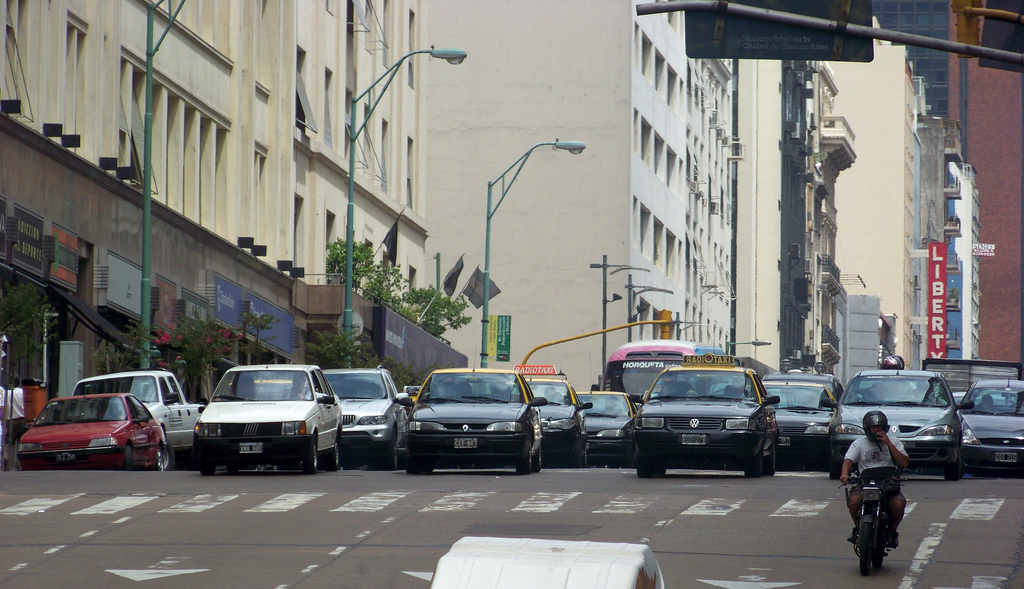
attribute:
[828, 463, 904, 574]
motorcycle — black 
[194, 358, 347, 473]
car — white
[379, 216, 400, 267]
flag — black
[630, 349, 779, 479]
car — black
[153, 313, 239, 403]
tree — green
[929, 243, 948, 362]
sign — red, white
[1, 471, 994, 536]
lines — white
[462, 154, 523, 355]
pole — green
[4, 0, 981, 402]
buildings — row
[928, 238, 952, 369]
sign — white, red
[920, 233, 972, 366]
liberty — White 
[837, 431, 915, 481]
shirt — white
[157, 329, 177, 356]
flowers — red